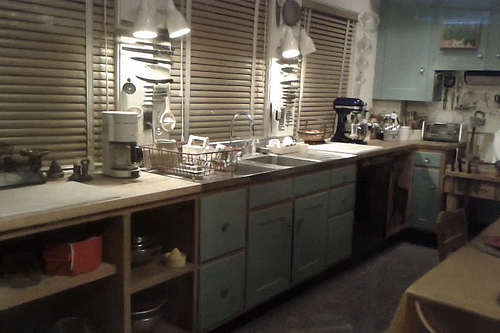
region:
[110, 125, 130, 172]
Coffe maker on the counter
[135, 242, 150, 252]
Metallic bowls in a shelf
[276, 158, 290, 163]
Sink on the right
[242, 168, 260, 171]
Sink on the left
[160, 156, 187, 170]
A dish rack on the counter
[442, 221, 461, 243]
A chair on the ground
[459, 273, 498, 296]
A table surface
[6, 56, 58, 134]
Window blinds down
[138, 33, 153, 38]
Light is switched on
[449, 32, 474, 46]
A painting on the cupboard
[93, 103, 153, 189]
white and black coffee pot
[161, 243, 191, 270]
white pointed fruit juicer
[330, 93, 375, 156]
black and silver mixer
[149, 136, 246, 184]
dish rack to hold dishes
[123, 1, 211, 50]
subtle lighting in kitchen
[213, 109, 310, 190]
stainless steel kitchen sink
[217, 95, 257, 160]
stainless steel kitchen faucet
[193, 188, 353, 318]
blue and wood kitchen cabinets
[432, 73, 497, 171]
wall of kitchen utencils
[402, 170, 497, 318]
kitchen table to eat on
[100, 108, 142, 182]
Coffee maker on the counter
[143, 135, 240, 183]
Dishes in th strainer beside the sink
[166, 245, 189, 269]
Manual juicer on the shelf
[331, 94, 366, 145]
Black mixer on the counter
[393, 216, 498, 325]
Yellow tablecloth on the table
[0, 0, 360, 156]
Blinds covering the windows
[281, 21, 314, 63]
Lamp on the wall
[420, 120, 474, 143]
Toaster oven on the counter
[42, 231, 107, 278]
Big red pot on the shelf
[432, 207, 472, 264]
Chair pushed in to the table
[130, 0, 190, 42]
White lights on wall.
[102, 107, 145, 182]
White coffee maker on counter.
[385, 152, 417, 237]
Towel hanging in front of oven.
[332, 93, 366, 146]
Dark blue and silver mixer.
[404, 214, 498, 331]
Tablecloth covering dining room table.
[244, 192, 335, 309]
Cabinets underneath sink.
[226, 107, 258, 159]
Curved silver faucet.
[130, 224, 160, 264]
Metal silver mixing bowls.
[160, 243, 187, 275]
Yellow lemon juicer.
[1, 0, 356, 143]
Blinds covering kitchen windows.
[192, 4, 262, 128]
blinds on a kitchen window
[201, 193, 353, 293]
cabinets in a kitchen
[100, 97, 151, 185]
coffe pot on a counter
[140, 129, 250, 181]
dish strainer on a counter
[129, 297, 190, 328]
pot on a shelf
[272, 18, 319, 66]
light on a wall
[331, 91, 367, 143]
blender on a counter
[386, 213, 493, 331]
table and chair in kitchen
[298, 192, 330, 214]
handle on cabinet door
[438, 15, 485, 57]
picture on a cabinet door